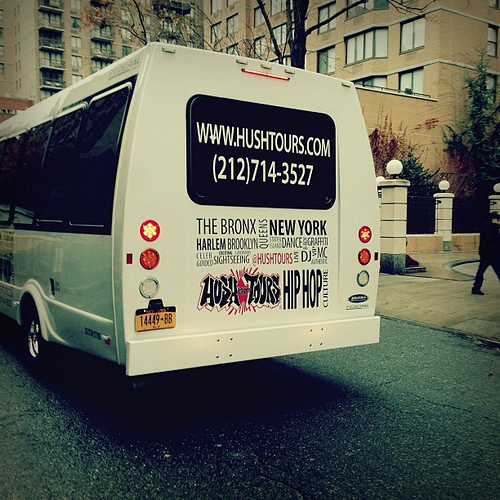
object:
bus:
[0, 41, 382, 377]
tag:
[135, 298, 177, 334]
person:
[468, 210, 500, 295]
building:
[10, 0, 203, 102]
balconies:
[38, 45, 67, 72]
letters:
[236, 127, 245, 146]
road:
[0, 313, 499, 498]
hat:
[484, 210, 498, 223]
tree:
[442, 42, 499, 210]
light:
[138, 276, 161, 298]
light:
[138, 246, 162, 268]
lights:
[383, 159, 402, 174]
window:
[70, 88, 128, 226]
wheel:
[17, 292, 45, 369]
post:
[377, 186, 408, 274]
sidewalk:
[377, 256, 500, 343]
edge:
[376, 313, 499, 344]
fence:
[407, 192, 437, 233]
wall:
[358, 86, 442, 179]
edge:
[408, 91, 440, 103]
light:
[438, 178, 452, 190]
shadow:
[53, 348, 360, 462]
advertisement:
[194, 119, 331, 185]